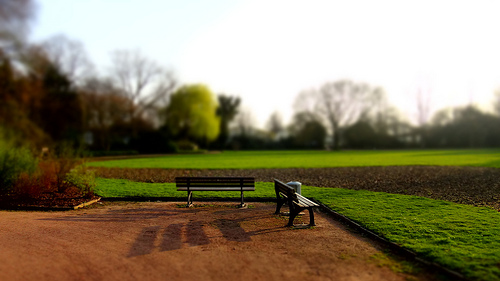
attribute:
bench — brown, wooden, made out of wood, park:
[272, 177, 319, 226]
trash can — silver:
[288, 180, 300, 201]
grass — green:
[70, 152, 495, 279]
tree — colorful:
[3, 59, 66, 153]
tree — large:
[32, 25, 179, 149]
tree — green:
[168, 84, 218, 150]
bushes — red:
[16, 151, 88, 204]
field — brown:
[3, 201, 454, 278]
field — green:
[66, 150, 497, 276]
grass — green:
[345, 189, 459, 242]